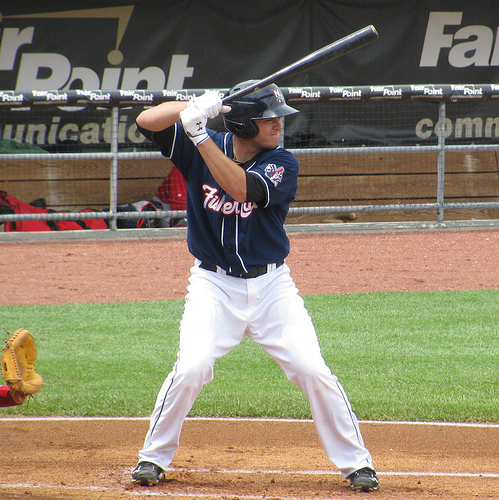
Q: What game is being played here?
A: Baseball.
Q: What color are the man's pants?
A: White.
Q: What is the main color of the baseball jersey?
A: Blue.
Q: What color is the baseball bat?
A: Black.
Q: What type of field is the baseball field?
A: Grass.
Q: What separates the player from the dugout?
A: A fence.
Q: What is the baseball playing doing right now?
A: Hitting.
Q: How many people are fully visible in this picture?
A: 1.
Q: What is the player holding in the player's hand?
A: A bat.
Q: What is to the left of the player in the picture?
A: A catcher's glove.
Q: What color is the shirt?
A: Blue.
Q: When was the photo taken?
A: In the daytime.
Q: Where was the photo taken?
A: In a baseball field.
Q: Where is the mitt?
A: In the photo.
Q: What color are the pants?
A: White.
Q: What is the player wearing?
A: Helmet.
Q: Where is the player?
A: At bat.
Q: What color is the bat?
A: Black.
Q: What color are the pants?
A: White.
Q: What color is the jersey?
A: Blue.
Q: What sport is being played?
A: Baseball.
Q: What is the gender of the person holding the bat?
A: Male.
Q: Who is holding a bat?
A: A man.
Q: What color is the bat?
A: Black.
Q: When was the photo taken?
A: During daylight hours.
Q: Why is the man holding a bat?
A: Getting ready to hit a ball.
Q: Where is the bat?
A: Above the batter's head.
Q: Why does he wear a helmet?
A: To protect his head.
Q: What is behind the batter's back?
A: The dugout.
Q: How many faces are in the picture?
A: 1.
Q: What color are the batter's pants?
A: White.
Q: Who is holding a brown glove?
A: The catcher.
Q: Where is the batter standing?
A: In the batter's box.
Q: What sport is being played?
A: Baseball.